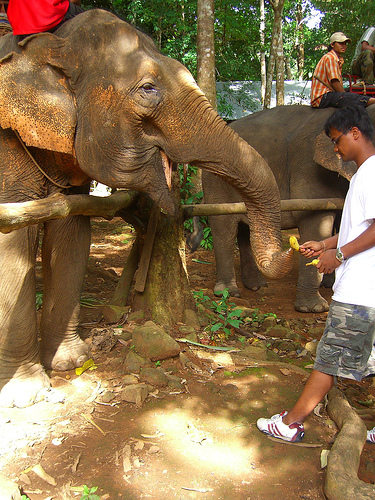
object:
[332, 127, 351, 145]
eyeglasses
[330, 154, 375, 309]
shirt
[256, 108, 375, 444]
man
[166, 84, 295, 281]
trunk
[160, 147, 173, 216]
mouth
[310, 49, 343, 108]
shirt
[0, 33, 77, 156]
ear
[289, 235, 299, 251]
banana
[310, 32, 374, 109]
man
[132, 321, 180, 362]
rock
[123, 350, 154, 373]
rock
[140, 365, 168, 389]
rock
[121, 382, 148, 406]
rock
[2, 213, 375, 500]
ground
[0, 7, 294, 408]
elephant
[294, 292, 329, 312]
foot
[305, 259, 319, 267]
banana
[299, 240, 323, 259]
hand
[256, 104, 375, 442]
boy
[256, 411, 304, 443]
shoe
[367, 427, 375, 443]
shoe